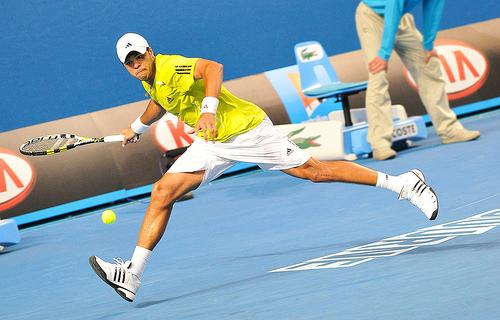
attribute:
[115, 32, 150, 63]
cap — white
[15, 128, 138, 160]
racket — black, white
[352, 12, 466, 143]
pants — tan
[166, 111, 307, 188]
shorts — white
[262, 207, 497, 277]
letters — white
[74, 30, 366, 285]
man — running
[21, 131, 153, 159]
racket — black, white, yellow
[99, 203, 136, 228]
ball — yellow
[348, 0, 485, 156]
person — standing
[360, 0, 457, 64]
blue shirt — long sleeved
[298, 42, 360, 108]
chair — Blue 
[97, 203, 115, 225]
ball — Yellow 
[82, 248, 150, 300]
shoe — white, black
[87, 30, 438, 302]
man — playing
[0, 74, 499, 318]
tennis court — blue